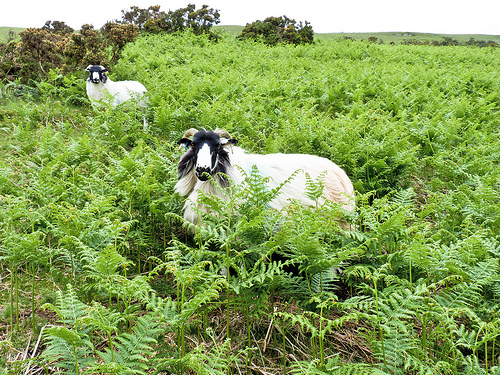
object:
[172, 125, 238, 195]
head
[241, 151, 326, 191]
goat's fur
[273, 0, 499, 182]
field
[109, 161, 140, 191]
fern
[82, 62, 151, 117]
goat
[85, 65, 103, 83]
black face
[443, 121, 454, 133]
ground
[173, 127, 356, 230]
fur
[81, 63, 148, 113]
fur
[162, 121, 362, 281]
goat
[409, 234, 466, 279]
fern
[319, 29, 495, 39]
hill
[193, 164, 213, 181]
snout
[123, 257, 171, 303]
green fern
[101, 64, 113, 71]
horn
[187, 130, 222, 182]
face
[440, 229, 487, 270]
fern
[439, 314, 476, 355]
fern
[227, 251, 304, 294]
fern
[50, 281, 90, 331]
fern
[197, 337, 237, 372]
fern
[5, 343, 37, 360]
ground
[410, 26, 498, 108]
grass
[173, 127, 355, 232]
sheep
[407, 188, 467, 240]
fern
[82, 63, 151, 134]
sheep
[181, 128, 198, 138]
horn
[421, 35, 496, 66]
fern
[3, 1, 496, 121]
distance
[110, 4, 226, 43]
tree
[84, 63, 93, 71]
horn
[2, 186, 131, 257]
ferns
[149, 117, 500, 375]
field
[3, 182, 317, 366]
field